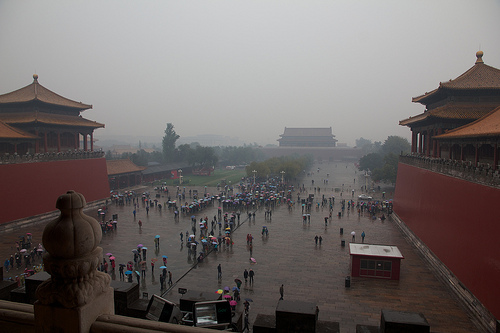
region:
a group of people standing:
[86, 168, 409, 331]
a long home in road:
[16, 76, 115, 255]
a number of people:
[139, 176, 429, 321]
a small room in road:
[334, 226, 429, 300]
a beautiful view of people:
[95, 105, 422, 327]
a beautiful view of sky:
[35, 15, 497, 143]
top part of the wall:
[43, 199, 128, 289]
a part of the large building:
[362, 73, 499, 331]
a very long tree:
[157, 105, 191, 167]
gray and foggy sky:
[2, 2, 494, 146]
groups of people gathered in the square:
[103, 183, 398, 297]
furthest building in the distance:
[277, 125, 339, 156]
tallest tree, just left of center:
[161, 121, 181, 166]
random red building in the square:
[347, 239, 406, 283]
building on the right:
[398, 50, 499, 173]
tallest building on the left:
[3, 75, 105, 168]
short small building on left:
[106, 155, 208, 192]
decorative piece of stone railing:
[31, 188, 116, 331]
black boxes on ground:
[116, 281, 436, 331]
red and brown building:
[3, 58, 140, 230]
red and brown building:
[367, 33, 498, 213]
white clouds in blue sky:
[40, 25, 101, 61]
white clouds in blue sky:
[113, 30, 136, 61]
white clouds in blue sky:
[193, 30, 251, 102]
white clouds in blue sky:
[245, 7, 298, 57]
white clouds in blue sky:
[323, 55, 363, 103]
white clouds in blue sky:
[366, 43, 402, 79]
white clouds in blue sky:
[175, 61, 212, 89]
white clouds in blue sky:
[81, 58, 125, 96]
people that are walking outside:
[65, 103, 406, 328]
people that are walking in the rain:
[85, 153, 419, 328]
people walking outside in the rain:
[117, 157, 370, 302]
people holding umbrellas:
[109, 146, 401, 300]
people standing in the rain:
[91, 154, 386, 282]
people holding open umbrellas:
[128, 173, 394, 310]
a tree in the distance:
[147, 81, 222, 211]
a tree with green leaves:
[143, 96, 210, 207]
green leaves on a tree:
[150, 114, 211, 190]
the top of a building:
[16, 73, 144, 251]